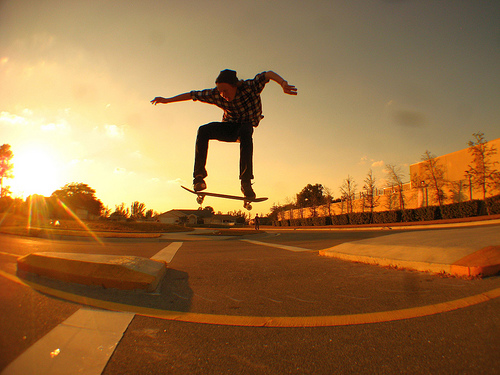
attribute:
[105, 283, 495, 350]
stripe — yellow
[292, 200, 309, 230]
tree — green, small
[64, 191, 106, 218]
tree — small, green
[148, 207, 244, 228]
house — white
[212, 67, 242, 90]
hat — black, beanie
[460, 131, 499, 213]
shrub — trimmed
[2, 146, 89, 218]
light — bright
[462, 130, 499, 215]
tree — bare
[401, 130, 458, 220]
tree — small, green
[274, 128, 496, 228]
building — low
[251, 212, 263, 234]
friend — boy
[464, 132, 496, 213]
tree — small, green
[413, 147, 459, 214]
tree — small, green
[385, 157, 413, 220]
tree — small, green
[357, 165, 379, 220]
tree — small, green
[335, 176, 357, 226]
tree — green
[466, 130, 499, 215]
tree — green, small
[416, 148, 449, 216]
tree — green, small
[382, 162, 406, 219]
tree — green, small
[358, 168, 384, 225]
tree — green, small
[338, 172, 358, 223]
tree — green, small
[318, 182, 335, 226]
tree — green, small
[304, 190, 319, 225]
tree — green, small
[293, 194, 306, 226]
tree — green, small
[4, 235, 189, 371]
stripe — thick, wide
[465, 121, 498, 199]
tree — green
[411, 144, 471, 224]
tree — green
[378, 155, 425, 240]
tree — green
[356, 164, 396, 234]
tree — green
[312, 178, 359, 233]
tree — green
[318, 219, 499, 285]
panel — flat, concrete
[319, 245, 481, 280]
angles — horizontal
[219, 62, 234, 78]
hat — black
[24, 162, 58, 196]
sun — shining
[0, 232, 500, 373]
pavement — flat, grey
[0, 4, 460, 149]
sky — darkening